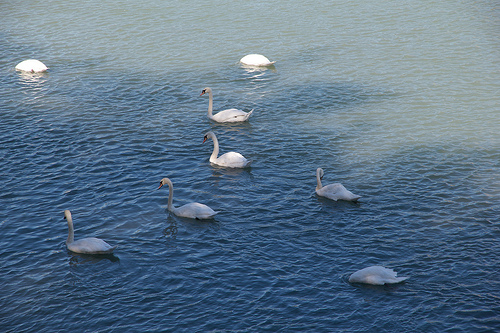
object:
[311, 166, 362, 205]
bird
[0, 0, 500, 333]
water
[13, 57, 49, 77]
bird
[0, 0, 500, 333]
ground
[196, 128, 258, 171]
bird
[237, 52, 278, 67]
bird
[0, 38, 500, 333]
shade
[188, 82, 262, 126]
birds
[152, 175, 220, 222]
bird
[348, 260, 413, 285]
bird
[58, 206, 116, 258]
bird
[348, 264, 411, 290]
bird